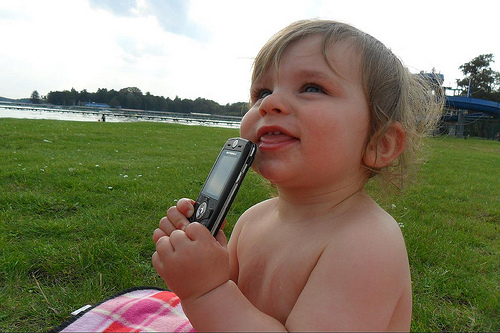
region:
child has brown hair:
[229, 18, 452, 175]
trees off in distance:
[44, 69, 246, 151]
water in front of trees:
[3, 98, 185, 145]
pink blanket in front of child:
[72, 236, 194, 328]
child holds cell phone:
[184, 131, 263, 241]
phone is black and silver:
[182, 143, 294, 248]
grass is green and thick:
[2, 138, 115, 253]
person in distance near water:
[93, 107, 115, 124]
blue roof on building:
[434, 88, 499, 140]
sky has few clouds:
[4, 39, 189, 89]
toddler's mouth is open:
[253, 129, 335, 162]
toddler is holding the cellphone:
[185, 125, 323, 251]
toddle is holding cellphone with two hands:
[154, 189, 223, 303]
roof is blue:
[449, 87, 498, 112]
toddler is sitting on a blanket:
[79, 284, 224, 332]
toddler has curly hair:
[365, 47, 443, 222]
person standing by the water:
[40, 96, 231, 141]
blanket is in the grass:
[63, 240, 220, 331]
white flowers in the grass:
[51, 126, 145, 208]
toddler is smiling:
[228, 86, 354, 203]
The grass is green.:
[3, 114, 498, 330]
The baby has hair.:
[228, 17, 448, 202]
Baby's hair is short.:
[226, 12, 448, 208]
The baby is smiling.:
[149, 7, 436, 331]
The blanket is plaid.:
[46, 277, 211, 332]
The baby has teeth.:
[230, 12, 452, 209]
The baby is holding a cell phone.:
[126, 12, 449, 307]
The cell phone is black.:
[183, 127, 260, 247]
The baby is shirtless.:
[141, 14, 440, 331]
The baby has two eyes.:
[236, 15, 408, 195]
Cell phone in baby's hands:
[149, 136, 256, 281]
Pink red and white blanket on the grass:
[54, 285, 197, 331]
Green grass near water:
[14, 149, 132, 234]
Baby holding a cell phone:
[174, 24, 419, 284]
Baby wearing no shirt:
[199, 16, 447, 328]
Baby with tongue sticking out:
[224, 29, 411, 179]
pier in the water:
[137, 111, 222, 130]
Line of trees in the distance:
[39, 86, 199, 116]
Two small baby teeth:
[261, 126, 284, 138]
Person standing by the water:
[94, 106, 111, 126]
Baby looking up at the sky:
[239, 19, 407, 189]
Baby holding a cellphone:
[155, 134, 258, 300]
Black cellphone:
[185, 135, 255, 225]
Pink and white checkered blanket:
[64, 289, 181, 327]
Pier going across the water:
[1, 103, 240, 129]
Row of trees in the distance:
[32, 86, 222, 115]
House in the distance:
[83, 101, 110, 111]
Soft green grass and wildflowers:
[6, 123, 163, 210]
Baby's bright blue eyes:
[299, 81, 327, 97]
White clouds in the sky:
[18, 13, 182, 78]